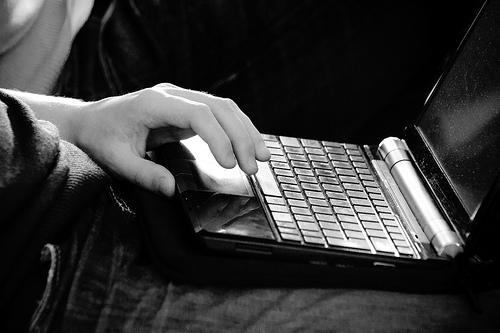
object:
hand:
[0, 81, 276, 199]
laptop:
[151, 0, 500, 277]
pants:
[0, 180, 499, 333]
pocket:
[21, 241, 64, 333]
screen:
[415, 0, 500, 221]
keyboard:
[243, 131, 417, 259]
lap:
[36, 227, 500, 333]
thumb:
[103, 145, 177, 199]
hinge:
[375, 135, 467, 261]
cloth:
[1, 0, 95, 95]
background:
[1, 0, 485, 144]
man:
[0, 77, 495, 332]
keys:
[331, 205, 355, 216]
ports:
[310, 260, 322, 266]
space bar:
[254, 160, 284, 197]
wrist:
[56, 94, 105, 146]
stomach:
[0, 89, 111, 257]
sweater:
[0, 91, 113, 321]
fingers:
[156, 94, 239, 172]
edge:
[189, 229, 463, 282]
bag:
[51, 0, 464, 296]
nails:
[151, 174, 172, 198]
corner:
[192, 228, 209, 248]